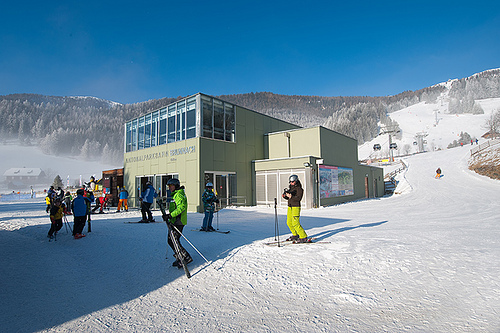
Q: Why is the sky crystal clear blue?
A: There are no clouds.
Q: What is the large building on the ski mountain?
A: Lodge.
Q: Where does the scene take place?
A: At a ski resort.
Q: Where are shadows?
A: On the snow.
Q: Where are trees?
A: In the distance.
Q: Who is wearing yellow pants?
A: Skier on right.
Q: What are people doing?
A: Skiing.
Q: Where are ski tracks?
A: On the snow.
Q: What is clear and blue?
A: Sky.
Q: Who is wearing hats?
A: Skiers.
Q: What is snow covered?
A: Trees.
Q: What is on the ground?
A: Snow.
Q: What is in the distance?
A: Mountains.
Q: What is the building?
A: Lodge.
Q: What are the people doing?
A: Skiing.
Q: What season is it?
A: Winter.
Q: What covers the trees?
A: Snow.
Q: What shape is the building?
A: Square.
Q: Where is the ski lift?
A: Background.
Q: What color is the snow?
A: White.